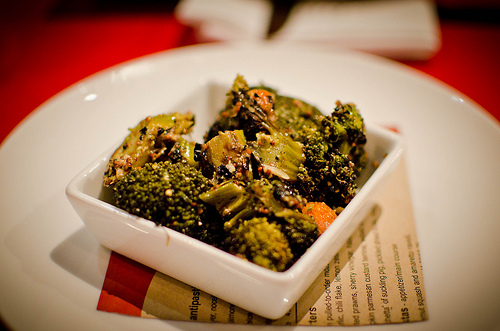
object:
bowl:
[57, 71, 412, 324]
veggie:
[219, 77, 291, 137]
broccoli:
[100, 74, 368, 277]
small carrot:
[298, 200, 336, 225]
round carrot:
[246, 85, 275, 117]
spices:
[114, 155, 150, 175]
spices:
[230, 151, 260, 176]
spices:
[227, 77, 297, 118]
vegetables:
[128, 87, 333, 246]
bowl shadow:
[52, 204, 389, 320]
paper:
[90, 113, 451, 327]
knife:
[262, 0, 299, 41]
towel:
[172, 1, 438, 61]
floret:
[109, 159, 216, 234]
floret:
[301, 100, 368, 199]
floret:
[221, 218, 296, 269]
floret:
[269, 209, 317, 247]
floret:
[229, 87, 274, 136]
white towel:
[144, 0, 459, 53]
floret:
[168, 111, 395, 202]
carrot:
[300, 197, 337, 234]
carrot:
[224, 86, 276, 116]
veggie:
[101, 72, 378, 270]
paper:
[96, 125, 436, 329]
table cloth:
[43, 24, 108, 48]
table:
[16, 9, 485, 328]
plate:
[0, 45, 500, 331]